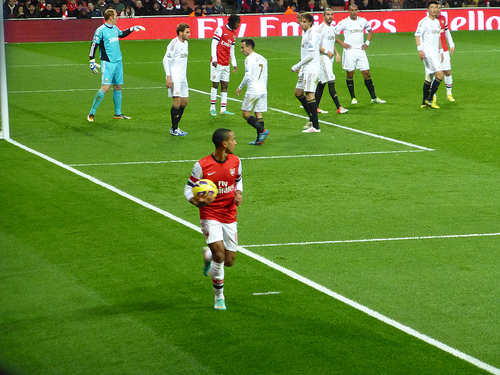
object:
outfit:
[86, 24, 132, 119]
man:
[182, 127, 245, 311]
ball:
[192, 179, 218, 204]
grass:
[0, 39, 497, 374]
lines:
[246, 232, 498, 248]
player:
[162, 22, 191, 137]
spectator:
[6, 3, 102, 17]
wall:
[106, 9, 499, 39]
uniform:
[86, 9, 145, 124]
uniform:
[211, 27, 238, 69]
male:
[334, 2, 387, 106]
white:
[335, 18, 371, 70]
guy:
[209, 15, 241, 116]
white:
[211, 66, 230, 81]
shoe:
[169, 128, 188, 136]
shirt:
[183, 155, 242, 223]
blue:
[88, 24, 123, 119]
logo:
[197, 16, 397, 40]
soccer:
[0, 37, 497, 312]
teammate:
[413, 0, 444, 110]